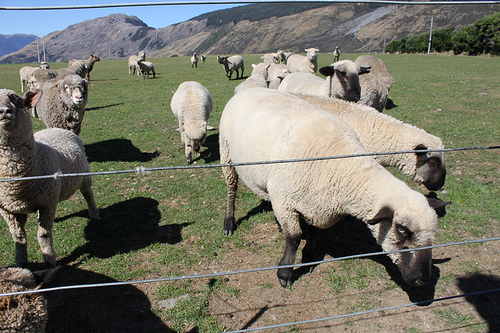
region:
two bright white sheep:
[211, 91, 460, 309]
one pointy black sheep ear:
[363, 201, 396, 228]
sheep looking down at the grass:
[160, 83, 216, 167]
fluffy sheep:
[0, 89, 112, 266]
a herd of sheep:
[1, 36, 463, 331]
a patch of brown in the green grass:
[186, 227, 493, 332]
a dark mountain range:
[15, 0, 494, 60]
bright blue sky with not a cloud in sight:
[0, 1, 248, 38]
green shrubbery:
[391, 12, 499, 52]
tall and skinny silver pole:
[423, 10, 440, 54]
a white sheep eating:
[225, 93, 387, 227]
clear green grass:
[106, 80, 188, 167]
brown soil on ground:
[204, 243, 390, 329]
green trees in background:
[400, 14, 496, 72]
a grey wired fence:
[39, 153, 497, 321]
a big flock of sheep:
[40, 46, 491, 158]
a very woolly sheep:
[37, 71, 129, 163]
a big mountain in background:
[30, 11, 281, 93]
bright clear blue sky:
[22, 13, 284, 48]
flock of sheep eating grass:
[127, 40, 490, 195]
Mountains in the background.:
[6, 3, 494, 59]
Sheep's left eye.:
[395, 217, 416, 244]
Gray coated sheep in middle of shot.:
[26, 72, 101, 139]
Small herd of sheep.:
[2, 37, 486, 327]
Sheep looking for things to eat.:
[219, 96, 434, 315]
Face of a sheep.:
[404, 138, 456, 195]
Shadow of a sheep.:
[43, 184, 212, 274]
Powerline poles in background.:
[30, 25, 59, 64]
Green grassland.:
[1, 57, 498, 328]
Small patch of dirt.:
[137, 217, 481, 331]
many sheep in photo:
[7, 49, 479, 331]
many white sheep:
[169, 50, 463, 238]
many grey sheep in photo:
[11, 56, 118, 330]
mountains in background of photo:
[14, 10, 481, 82]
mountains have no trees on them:
[21, 14, 406, 56]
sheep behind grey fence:
[8, 151, 498, 326]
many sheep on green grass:
[27, 46, 421, 328]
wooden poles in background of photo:
[17, 25, 77, 79]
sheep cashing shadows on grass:
[8, 48, 223, 331]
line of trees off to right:
[388, 16, 498, 57]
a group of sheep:
[15, 10, 491, 285]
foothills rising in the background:
[30, 10, 400, 72]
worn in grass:
[182, 242, 344, 329]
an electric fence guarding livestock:
[356, 185, 497, 328]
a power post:
[420, 15, 459, 72]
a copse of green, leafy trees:
[376, 22, 497, 45]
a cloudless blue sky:
[10, 13, 65, 38]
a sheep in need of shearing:
[48, 66, 113, 121]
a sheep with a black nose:
[314, 57, 391, 100]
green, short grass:
[104, 79, 157, 133]